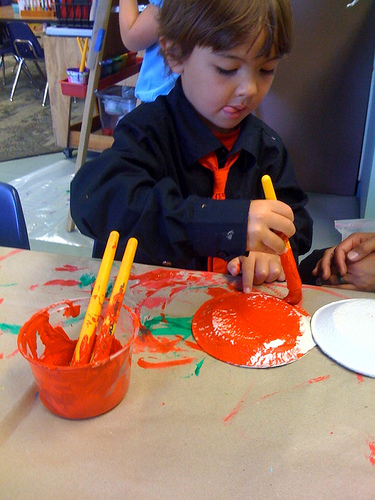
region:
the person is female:
[151, 5, 299, 156]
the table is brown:
[168, 418, 304, 482]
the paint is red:
[10, 285, 158, 431]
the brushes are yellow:
[62, 226, 145, 363]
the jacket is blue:
[56, 78, 316, 288]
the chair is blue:
[2, 0, 56, 108]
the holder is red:
[55, 73, 94, 99]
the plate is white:
[295, 293, 371, 384]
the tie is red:
[202, 150, 238, 286]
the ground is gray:
[23, 171, 68, 209]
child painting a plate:
[86, 7, 345, 280]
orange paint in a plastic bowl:
[22, 293, 140, 419]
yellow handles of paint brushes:
[68, 226, 138, 364]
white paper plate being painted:
[191, 290, 316, 368]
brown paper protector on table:
[3, 247, 373, 498]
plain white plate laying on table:
[314, 296, 374, 379]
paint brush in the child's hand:
[260, 175, 316, 306]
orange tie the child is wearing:
[198, 143, 240, 273]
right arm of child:
[77, 111, 295, 255]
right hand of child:
[221, 192, 297, 256]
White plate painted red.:
[180, 288, 293, 380]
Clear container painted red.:
[19, 303, 134, 423]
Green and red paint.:
[132, 303, 181, 353]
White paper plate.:
[310, 299, 367, 390]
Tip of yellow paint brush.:
[237, 152, 309, 201]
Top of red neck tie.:
[177, 144, 252, 218]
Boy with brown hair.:
[116, 6, 311, 145]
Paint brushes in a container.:
[59, 26, 89, 86]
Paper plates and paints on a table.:
[5, 281, 331, 467]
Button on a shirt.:
[219, 224, 237, 242]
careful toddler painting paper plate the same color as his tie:
[60, 0, 328, 376]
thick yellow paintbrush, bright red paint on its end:
[259, 168, 304, 315]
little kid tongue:
[212, 97, 248, 122]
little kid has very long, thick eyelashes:
[207, 61, 275, 78]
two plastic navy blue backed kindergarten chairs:
[0, 18, 47, 252]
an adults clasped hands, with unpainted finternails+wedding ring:
[311, 219, 374, 301]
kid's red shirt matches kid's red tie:
[193, 125, 245, 275]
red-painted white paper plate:
[185, 286, 320, 373]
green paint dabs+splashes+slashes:
[59, 267, 209, 390]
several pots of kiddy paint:
[56, 46, 144, 99]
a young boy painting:
[73, 10, 326, 323]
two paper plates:
[184, 290, 374, 372]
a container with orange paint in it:
[11, 295, 131, 416]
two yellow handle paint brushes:
[67, 226, 139, 371]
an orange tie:
[196, 145, 245, 277]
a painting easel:
[56, 3, 132, 234]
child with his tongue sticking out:
[151, 5, 286, 131]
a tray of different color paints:
[58, 43, 141, 94]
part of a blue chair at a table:
[4, 176, 36, 261]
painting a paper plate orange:
[193, 287, 323, 368]